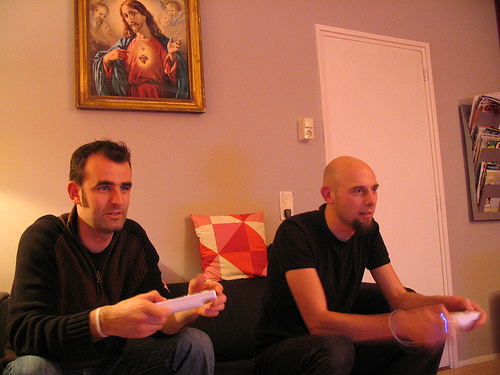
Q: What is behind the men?
A: A pillow.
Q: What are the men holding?
A: Video game controllers.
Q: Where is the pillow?
A: Behind the men.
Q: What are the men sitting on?
A: The sofa.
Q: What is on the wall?
A: A painting.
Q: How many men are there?
A: Two.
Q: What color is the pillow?
A: Orange, red, white, and pink.